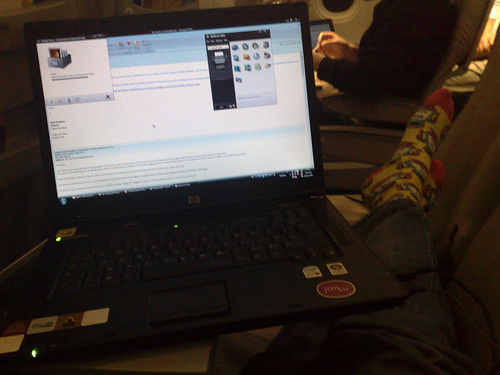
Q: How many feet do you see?
A: 2.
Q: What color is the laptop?
A: Black.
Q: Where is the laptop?
A: On the table.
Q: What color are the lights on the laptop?
A: Green.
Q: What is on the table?
A: A laptop.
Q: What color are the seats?
A: Brown.